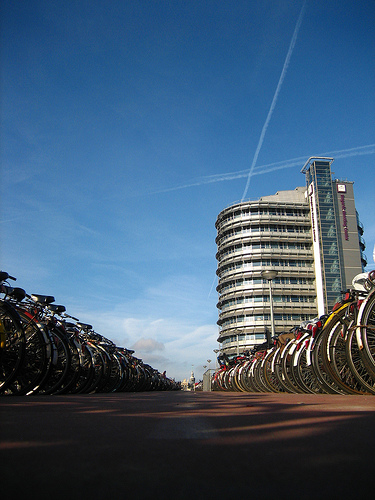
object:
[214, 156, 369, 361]
building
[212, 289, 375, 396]
tire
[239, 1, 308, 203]
contrail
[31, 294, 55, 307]
seat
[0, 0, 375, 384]
blue sky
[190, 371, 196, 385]
tall tower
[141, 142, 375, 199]
contrail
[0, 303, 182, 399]
tire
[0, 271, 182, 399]
bike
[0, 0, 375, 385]
cloud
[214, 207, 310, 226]
windows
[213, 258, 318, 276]
windows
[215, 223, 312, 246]
windows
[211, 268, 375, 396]
bicycles